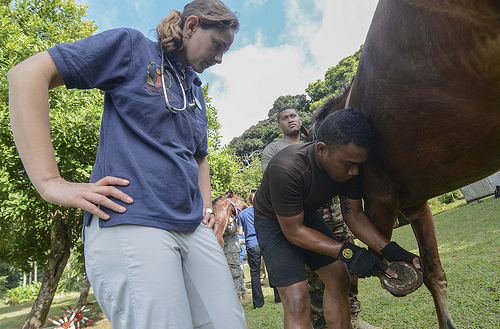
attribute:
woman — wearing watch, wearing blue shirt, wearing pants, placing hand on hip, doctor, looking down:
[9, 1, 242, 328]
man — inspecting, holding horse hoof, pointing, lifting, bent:
[253, 111, 420, 327]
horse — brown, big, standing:
[319, 0, 498, 325]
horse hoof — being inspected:
[379, 254, 429, 298]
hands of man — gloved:
[335, 242, 424, 279]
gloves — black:
[338, 247, 418, 276]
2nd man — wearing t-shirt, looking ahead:
[252, 107, 319, 172]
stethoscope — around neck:
[157, 34, 202, 111]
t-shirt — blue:
[51, 30, 204, 231]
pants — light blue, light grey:
[80, 212, 250, 328]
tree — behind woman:
[1, 3, 124, 329]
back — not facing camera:
[239, 210, 256, 246]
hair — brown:
[150, 1, 240, 53]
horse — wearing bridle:
[213, 191, 247, 246]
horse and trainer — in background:
[214, 191, 283, 304]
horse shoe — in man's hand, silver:
[380, 268, 427, 295]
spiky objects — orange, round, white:
[47, 303, 97, 327]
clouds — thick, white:
[210, 3, 377, 141]